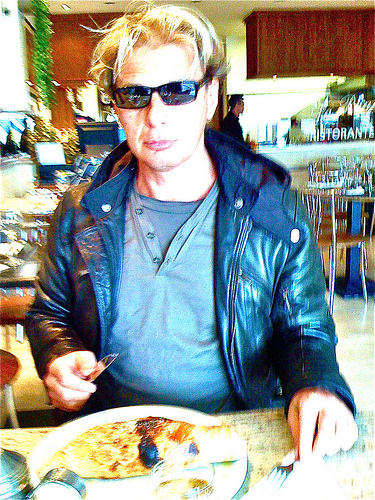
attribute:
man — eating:
[25, 6, 360, 457]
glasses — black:
[104, 74, 213, 110]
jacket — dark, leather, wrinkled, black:
[27, 140, 360, 418]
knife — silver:
[89, 351, 118, 386]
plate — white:
[21, 403, 249, 499]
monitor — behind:
[35, 138, 73, 174]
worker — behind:
[220, 93, 255, 146]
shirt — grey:
[103, 168, 243, 414]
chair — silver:
[303, 186, 371, 312]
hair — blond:
[80, 3, 231, 82]